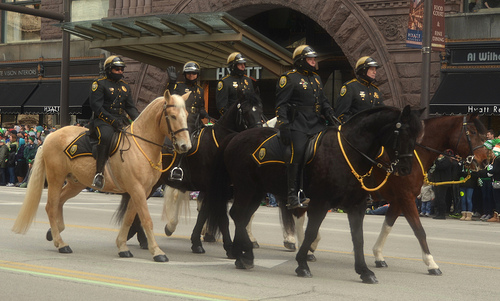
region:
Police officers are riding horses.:
[21, 37, 483, 275]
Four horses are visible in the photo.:
[25, 79, 475, 281]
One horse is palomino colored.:
[16, 83, 199, 268]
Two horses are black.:
[156, 80, 420, 280]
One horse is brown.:
[365, 106, 482, 278]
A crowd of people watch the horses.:
[2, 117, 61, 189]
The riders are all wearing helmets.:
[82, 45, 392, 100]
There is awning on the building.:
[44, 11, 306, 81]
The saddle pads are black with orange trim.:
[255, 122, 331, 171]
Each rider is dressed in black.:
[272, 45, 341, 224]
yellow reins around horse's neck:
[128, 121, 175, 181]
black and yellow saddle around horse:
[64, 131, 122, 166]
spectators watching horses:
[2, 120, 47, 172]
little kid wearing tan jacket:
[420, 178, 433, 218]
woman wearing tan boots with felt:
[458, 208, 475, 224]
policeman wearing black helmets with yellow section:
[100, 51, 202, 78]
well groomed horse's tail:
[5, 145, 57, 237]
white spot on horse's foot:
[416, 251, 441, 274]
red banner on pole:
[430, 4, 460, 71]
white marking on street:
[112, 247, 321, 284]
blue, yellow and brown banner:
[401, 2, 430, 50]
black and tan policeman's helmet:
[90, 52, 130, 73]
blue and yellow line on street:
[0, 254, 212, 299]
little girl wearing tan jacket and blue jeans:
[418, 174, 444, 212]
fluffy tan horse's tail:
[6, 131, 56, 240]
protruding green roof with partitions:
[60, 12, 237, 47]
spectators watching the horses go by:
[1, 118, 47, 183]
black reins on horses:
[118, 89, 202, 156]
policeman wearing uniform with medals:
[277, 38, 330, 227]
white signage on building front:
[33, 94, 68, 114]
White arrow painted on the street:
[106, 252, 293, 273]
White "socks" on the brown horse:
[371, 221, 439, 271]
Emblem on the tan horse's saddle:
[62, 141, 83, 159]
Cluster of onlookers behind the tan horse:
[2, 118, 50, 188]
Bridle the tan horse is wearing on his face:
[161, 109, 192, 136]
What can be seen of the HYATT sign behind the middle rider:
[212, 62, 263, 83]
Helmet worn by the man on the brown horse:
[351, 55, 379, 72]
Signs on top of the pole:
[406, 7, 450, 55]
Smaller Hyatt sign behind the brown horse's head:
[464, 105, 494, 115]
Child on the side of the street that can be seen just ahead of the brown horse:
[415, 181, 437, 218]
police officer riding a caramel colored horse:
[16, 51, 203, 268]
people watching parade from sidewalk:
[0, 105, 60, 200]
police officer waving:
[160, 52, 212, 134]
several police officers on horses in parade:
[25, 45, 455, 280]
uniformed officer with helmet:
[265, 35, 345, 217]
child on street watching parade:
[405, 167, 440, 222]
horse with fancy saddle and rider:
[0, 87, 195, 222]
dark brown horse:
[205, 100, 421, 285]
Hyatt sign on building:
[190, 50, 280, 87]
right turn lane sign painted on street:
[111, 235, 291, 283]